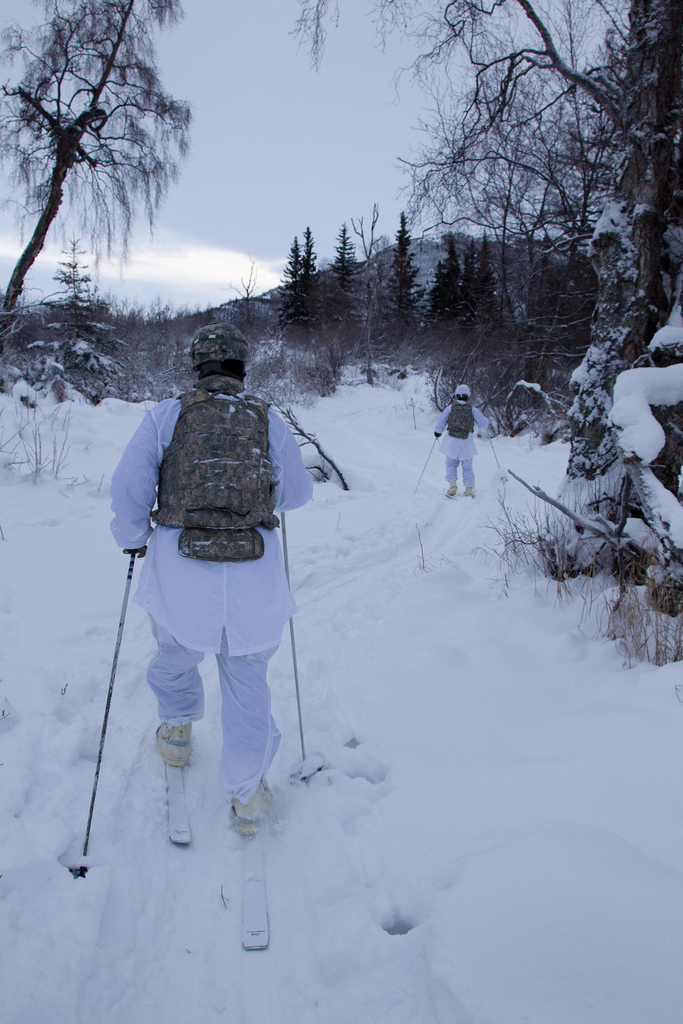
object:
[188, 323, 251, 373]
hat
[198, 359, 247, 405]
head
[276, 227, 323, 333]
tree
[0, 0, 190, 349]
tree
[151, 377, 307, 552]
backpack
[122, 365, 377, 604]
back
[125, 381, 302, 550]
back pack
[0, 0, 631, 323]
sky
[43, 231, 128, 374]
tree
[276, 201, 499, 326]
forest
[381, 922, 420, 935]
print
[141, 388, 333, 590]
backpack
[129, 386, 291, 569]
backpack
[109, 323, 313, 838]
man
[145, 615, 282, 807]
pants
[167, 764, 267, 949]
skis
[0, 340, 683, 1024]
snow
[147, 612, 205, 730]
leg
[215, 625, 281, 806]
leg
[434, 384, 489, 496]
man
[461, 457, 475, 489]
leg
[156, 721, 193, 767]
foot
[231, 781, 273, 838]
foot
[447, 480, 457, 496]
foot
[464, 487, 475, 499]
foot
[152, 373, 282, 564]
backpack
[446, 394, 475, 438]
backpack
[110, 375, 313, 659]
coat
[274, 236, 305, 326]
tree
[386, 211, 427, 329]
tree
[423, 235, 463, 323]
tree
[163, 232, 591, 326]
mountain